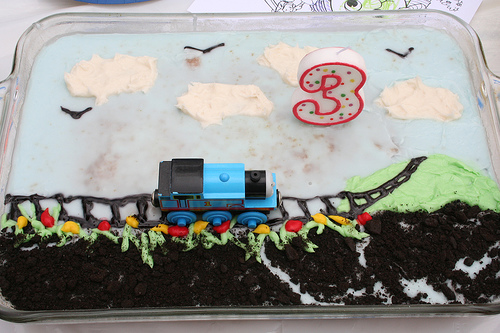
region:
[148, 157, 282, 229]
Little Toy Train Engine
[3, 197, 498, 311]
Chocolate Oreo Cookie Crumbs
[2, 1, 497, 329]
Birthday cake for a 3 year old with toy train on track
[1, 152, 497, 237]
Make Believe Railroad Track made out of Frosting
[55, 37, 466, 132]
Clouds and 3 Birds in Sky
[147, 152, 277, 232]
Blue Toy Engine even has Blue Tires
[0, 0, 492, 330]
A Really Fun Birthday Cake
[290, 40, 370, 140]
Number 3 Candle has never been Lit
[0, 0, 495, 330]
Cake Baked in Glass Bakeware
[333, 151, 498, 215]
Green Mound of Frosting is Hill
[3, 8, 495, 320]
Birthday cake in glass cake pan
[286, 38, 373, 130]
White candle in shape of 3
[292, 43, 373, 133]
White candle with red outline and colored dots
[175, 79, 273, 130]
White clouds made from icing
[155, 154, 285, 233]
Blue and black train on cake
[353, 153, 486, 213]
Grass made of green icing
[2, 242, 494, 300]
Dirt made of crumbled cake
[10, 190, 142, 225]
Train tracks made of black icing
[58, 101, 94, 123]
Birds made of black icing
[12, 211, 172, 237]
Flowers made of red and yellow icing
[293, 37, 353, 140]
Number 3 candle on cake.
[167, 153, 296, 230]
Blue train sitting on cake.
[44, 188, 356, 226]
Train on train tracks.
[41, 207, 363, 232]
Orange and yellow candy on cake.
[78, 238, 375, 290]
Crushed oreos on cake.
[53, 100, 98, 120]
Black bird on cake.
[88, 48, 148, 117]
White cloud on cake.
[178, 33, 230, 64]
Black bird on cake.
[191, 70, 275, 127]
White cloud on cake.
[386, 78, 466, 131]
White cloud on cake.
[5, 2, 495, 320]
the cake is in a dish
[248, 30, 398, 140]
the number on the cake is 3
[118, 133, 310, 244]
a train on the cake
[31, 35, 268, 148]
the clouds are white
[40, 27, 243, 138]
birds on the cake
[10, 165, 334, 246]
the tracks are black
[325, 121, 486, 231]
the mountain is green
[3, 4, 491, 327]
the dish is glass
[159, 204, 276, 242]
the wheels are blue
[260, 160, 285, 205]
the train has a face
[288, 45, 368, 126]
The candle is shaped as the number three.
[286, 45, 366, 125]
The candle is outlined in red.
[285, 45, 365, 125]
The candle is white.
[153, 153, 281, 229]
Thomas The Tank Engine is on the cake.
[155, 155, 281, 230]
The train is blue.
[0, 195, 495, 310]
The cake contains cookie crumbs.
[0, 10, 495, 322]
The cake pan is glass.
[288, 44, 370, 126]
The candle has not been lit yet.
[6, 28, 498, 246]
The frosting is blue, white, and green.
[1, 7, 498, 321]
The cake and pan are rectangular.